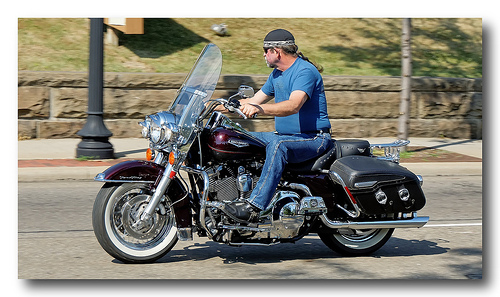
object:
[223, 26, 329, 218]
man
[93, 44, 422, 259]
motorcycle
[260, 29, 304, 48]
hat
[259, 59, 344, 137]
shirt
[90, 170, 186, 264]
wheel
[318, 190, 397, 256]
wheel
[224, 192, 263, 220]
foot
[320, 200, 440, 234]
muffler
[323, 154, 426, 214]
saddle bag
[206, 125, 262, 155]
gas tank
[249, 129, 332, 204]
pants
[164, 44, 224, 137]
windshield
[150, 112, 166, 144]
light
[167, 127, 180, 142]
light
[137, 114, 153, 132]
light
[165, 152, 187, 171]
turn signal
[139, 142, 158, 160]
turn signal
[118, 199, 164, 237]
spokes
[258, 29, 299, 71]
head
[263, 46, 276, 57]
sunglasses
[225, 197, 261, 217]
boots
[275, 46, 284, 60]
ear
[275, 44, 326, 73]
hair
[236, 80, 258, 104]
mirror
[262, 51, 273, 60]
nose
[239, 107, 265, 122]
hand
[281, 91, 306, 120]
elbow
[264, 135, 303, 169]
knee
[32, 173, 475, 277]
road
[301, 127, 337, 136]
belt